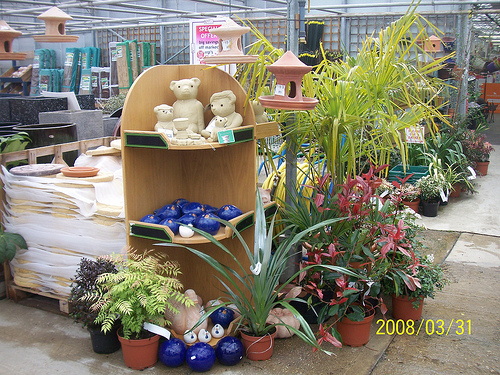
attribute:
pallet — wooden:
[12, 276, 76, 314]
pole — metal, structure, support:
[285, 113, 301, 293]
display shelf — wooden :
[112, 59, 262, 311]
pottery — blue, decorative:
[192, 212, 227, 237]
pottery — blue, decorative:
[214, 200, 240, 227]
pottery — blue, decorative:
[184, 199, 214, 215]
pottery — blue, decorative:
[158, 215, 180, 240]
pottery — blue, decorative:
[137, 210, 162, 227]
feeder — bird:
[30, 28, 107, 107]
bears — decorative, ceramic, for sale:
[119, 66, 271, 166]